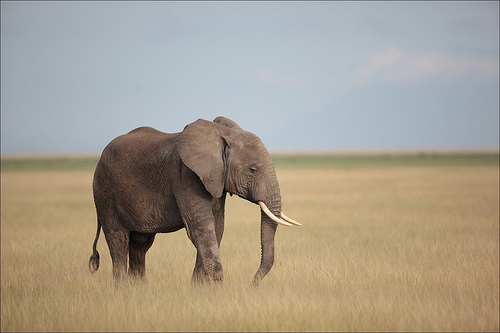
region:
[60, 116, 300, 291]
large elephant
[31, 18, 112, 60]
white clouds in blue sky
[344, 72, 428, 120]
white clouds in blue sky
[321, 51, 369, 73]
white clouds in blue sky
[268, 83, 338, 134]
white clouds in blue sky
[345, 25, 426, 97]
white clouds in blue sky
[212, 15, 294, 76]
white clouds in blue sky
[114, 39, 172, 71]
white clouds in blue sky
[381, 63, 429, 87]
white clouds in blue sky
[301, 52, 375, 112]
white clouds in blue sky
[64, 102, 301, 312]
brown elephant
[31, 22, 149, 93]
white clouds in blue sky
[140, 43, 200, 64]
white clouds in blue sky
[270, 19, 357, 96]
white clouds in blue sky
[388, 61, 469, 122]
white clouds in blue sky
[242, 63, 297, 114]
white clouds in blue sky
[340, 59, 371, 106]
white clouds in blue sky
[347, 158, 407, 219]
brown grass on ground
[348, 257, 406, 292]
brown grass on ground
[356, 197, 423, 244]
brown grass on ground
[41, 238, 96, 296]
brown grass on ground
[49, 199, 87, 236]
brown grass on ground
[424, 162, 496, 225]
brown grass on ground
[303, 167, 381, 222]
brown grass on ground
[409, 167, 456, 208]
brown grass on ground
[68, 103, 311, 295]
One elephant in a field.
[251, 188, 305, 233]
The tusks on the elephant.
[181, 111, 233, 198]
The elephant's right ear.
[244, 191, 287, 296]
The long trunk of an elephant.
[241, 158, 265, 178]
The right eye of an elephant.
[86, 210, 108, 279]
An elephant's tail.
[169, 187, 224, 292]
An elephants right front leg.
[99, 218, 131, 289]
An elephant's right back leg.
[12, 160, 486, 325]
A field of tall brown grass.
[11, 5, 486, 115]
The sky is clear blue.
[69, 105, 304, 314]
elephant in the prarie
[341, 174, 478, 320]
brown grasses in a plain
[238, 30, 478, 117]
blue sky in the distance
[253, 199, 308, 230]
tusks on an elephant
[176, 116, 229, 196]
right ear on an elephant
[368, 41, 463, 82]
white cloud in the sky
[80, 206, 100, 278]
tail of an elephant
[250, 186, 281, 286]
trunk of an elephant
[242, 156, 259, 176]
right eye of an elephant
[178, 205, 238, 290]
front legs of an elephant